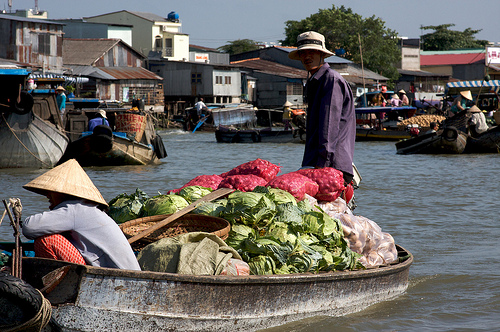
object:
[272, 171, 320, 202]
bag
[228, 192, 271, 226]
cabbage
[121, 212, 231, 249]
basket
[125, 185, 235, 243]
oar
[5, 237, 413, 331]
boat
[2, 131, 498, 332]
water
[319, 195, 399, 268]
bag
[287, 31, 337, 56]
hat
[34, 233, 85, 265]
pants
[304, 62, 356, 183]
shirt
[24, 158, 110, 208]
hat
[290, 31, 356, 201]
man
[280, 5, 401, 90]
tree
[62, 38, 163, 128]
building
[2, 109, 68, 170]
boat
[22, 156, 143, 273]
woman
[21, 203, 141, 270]
shirt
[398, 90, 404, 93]
hat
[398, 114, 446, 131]
potatoes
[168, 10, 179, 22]
person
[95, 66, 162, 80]
roof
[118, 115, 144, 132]
letters